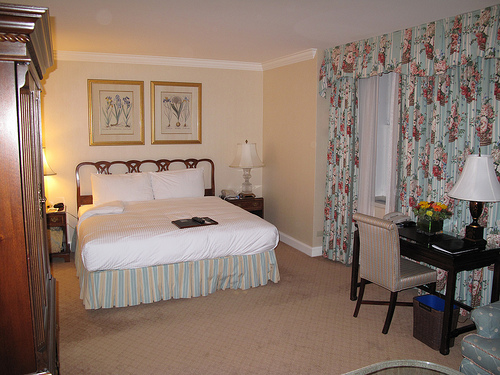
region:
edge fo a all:
[293, 134, 320, 166]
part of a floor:
[270, 333, 297, 367]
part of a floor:
[322, 290, 339, 314]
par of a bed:
[193, 248, 215, 276]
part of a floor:
[282, 315, 322, 352]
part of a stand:
[334, 242, 361, 285]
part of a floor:
[303, 335, 323, 363]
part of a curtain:
[338, 242, 354, 269]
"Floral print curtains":
[318, 8, 498, 309]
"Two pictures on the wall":
[75, 70, 213, 151]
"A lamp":
[445, 147, 498, 249]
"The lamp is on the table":
[342, 147, 499, 364]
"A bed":
[67, 145, 302, 323]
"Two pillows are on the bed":
[67, 154, 283, 316]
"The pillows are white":
[79, 153, 220, 213]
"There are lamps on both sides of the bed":
[27, 118, 291, 325]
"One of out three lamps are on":
[4, 118, 496, 351]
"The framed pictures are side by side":
[69, 50, 238, 159]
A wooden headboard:
[73, 160, 219, 210]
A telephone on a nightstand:
[219, 187, 240, 202]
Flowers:
[411, 199, 451, 221]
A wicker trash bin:
[411, 291, 460, 354]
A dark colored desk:
[351, 198, 498, 358]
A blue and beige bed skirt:
[74, 230, 282, 311]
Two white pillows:
[89, 170, 206, 203]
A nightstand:
[226, 196, 264, 225]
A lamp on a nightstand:
[224, 138, 266, 214]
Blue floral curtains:
[319, 5, 498, 305]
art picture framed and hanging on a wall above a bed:
[150, 78, 202, 144]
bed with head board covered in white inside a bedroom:
[73, 158, 281, 311]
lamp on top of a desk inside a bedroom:
[447, 147, 499, 248]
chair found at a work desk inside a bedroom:
[350, 210, 438, 335]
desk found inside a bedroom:
[351, 217, 498, 354]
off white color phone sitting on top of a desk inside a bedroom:
[381, 210, 411, 226]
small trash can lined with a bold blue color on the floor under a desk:
[411, 292, 456, 350]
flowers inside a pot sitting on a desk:
[413, 200, 450, 235]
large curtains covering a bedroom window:
[318, 5, 498, 331]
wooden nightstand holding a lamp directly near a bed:
[223, 194, 263, 217]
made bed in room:
[62, 146, 284, 310]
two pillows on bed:
[83, 165, 215, 210]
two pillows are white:
[87, 167, 210, 204]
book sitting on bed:
[171, 210, 216, 230]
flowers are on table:
[405, 190, 452, 242]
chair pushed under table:
[341, 210, 443, 340]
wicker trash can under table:
[403, 288, 465, 356]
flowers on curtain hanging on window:
[311, 9, 498, 315]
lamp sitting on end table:
[227, 137, 267, 199]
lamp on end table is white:
[226, 135, 266, 199]